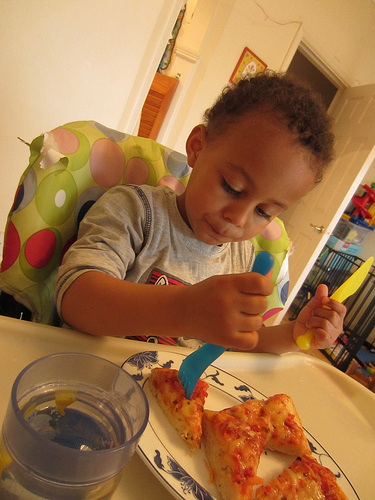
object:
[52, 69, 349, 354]
child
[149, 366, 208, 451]
pizza slice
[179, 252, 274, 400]
fork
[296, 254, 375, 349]
knife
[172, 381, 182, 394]
sauce